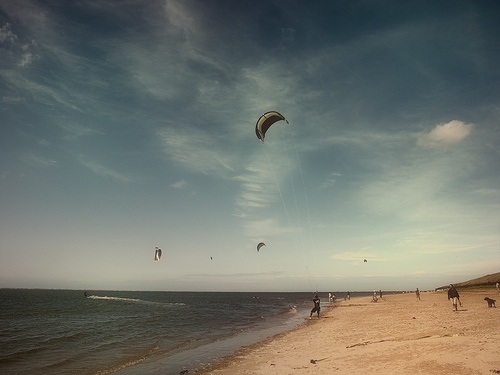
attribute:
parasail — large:
[254, 109, 292, 145]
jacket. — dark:
[446, 279, 461, 298]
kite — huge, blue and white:
[254, 107, 291, 142]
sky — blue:
[2, 0, 499, 291]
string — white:
[258, 123, 320, 295]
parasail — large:
[248, 100, 303, 167]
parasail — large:
[151, 234, 172, 274]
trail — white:
[78, 283, 192, 315]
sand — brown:
[303, 331, 413, 359]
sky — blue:
[114, 225, 198, 275]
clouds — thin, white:
[22, 21, 478, 237]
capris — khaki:
[442, 289, 468, 307]